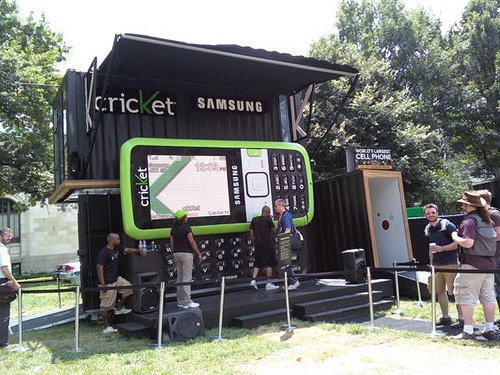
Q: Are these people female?
A: No, they are both male and female.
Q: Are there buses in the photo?
A: No, there are no buses.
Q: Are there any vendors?
A: No, there are no vendors.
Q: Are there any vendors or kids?
A: No, there are no vendors or kids.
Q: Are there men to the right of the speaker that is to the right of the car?
A: Yes, there is a man to the right of the speaker.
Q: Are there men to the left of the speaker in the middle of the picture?
A: No, the man is to the right of the speaker.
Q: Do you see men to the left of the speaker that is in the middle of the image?
A: No, the man is to the right of the speaker.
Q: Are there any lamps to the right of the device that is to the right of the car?
A: No, there is a man to the right of the speaker.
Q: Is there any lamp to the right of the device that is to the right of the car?
A: No, there is a man to the right of the speaker.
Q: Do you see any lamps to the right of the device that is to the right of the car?
A: No, there is a man to the right of the speaker.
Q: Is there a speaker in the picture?
A: Yes, there is a speaker.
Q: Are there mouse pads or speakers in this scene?
A: Yes, there is a speaker.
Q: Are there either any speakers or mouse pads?
A: Yes, there is a speaker.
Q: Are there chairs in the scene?
A: No, there are no chairs.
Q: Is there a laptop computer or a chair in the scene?
A: No, there are no chairs or laptops.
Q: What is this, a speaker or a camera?
A: This is a speaker.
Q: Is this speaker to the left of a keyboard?
A: No, the speaker is to the left of a man.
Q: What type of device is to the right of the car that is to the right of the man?
A: The device is a speaker.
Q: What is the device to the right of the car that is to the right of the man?
A: The device is a speaker.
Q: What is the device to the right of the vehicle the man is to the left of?
A: The device is a speaker.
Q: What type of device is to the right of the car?
A: The device is a speaker.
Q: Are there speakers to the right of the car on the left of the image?
A: Yes, there is a speaker to the right of the car.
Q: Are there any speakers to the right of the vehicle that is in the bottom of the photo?
A: Yes, there is a speaker to the right of the car.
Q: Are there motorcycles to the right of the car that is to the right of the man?
A: No, there is a speaker to the right of the car.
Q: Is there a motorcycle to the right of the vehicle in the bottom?
A: No, there is a speaker to the right of the car.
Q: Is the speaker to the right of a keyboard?
A: No, the speaker is to the right of a car.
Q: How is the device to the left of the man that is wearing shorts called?
A: The device is a speaker.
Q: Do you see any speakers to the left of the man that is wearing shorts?
A: Yes, there is a speaker to the left of the man.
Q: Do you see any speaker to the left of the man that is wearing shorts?
A: Yes, there is a speaker to the left of the man.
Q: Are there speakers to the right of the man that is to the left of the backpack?
A: No, the speaker is to the left of the man.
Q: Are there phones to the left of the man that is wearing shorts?
A: No, there is a speaker to the left of the man.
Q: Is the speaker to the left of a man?
A: Yes, the speaker is to the left of a man.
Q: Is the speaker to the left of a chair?
A: No, the speaker is to the left of a man.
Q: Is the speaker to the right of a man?
A: No, the speaker is to the left of a man.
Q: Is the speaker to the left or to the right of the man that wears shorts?
A: The speaker is to the left of the man.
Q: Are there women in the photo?
A: Yes, there is a woman.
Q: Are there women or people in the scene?
A: Yes, there is a woman.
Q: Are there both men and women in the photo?
A: Yes, there are both a woman and a man.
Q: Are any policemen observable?
A: No, there are no policemen.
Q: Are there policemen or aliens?
A: No, there are no policemen or aliens.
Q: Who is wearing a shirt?
A: The woman is wearing a shirt.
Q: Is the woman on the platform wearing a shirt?
A: Yes, the woman is wearing a shirt.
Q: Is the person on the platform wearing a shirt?
A: Yes, the woman is wearing a shirt.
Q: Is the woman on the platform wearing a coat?
A: No, the woman is wearing a shirt.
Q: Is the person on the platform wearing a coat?
A: No, the woman is wearing a shirt.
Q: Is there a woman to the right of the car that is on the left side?
A: Yes, there is a woman to the right of the car.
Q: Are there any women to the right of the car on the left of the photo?
A: Yes, there is a woman to the right of the car.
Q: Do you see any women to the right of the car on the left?
A: Yes, there is a woman to the right of the car.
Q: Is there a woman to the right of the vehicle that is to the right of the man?
A: Yes, there is a woman to the right of the car.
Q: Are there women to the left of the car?
A: No, the woman is to the right of the car.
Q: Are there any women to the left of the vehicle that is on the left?
A: No, the woman is to the right of the car.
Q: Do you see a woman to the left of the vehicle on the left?
A: No, the woman is to the right of the car.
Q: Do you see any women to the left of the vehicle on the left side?
A: No, the woman is to the right of the car.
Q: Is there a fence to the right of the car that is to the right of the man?
A: No, there is a woman to the right of the car.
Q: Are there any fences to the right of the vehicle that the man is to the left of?
A: No, there is a woman to the right of the car.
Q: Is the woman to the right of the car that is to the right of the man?
A: Yes, the woman is to the right of the car.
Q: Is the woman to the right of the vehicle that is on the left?
A: Yes, the woman is to the right of the car.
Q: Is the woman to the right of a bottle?
A: No, the woman is to the right of the car.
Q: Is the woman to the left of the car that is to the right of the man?
A: No, the woman is to the right of the car.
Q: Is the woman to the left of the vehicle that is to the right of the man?
A: No, the woman is to the right of the car.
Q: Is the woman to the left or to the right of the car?
A: The woman is to the right of the car.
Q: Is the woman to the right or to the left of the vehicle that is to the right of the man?
A: The woman is to the right of the car.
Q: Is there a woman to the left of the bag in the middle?
A: Yes, there is a woman to the left of the bag.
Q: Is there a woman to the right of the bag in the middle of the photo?
A: No, the woman is to the left of the bag.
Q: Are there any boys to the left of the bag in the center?
A: No, there is a woman to the left of the bag.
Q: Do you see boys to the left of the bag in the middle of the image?
A: No, there is a woman to the left of the bag.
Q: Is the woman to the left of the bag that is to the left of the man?
A: Yes, the woman is to the left of the bag.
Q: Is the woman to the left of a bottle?
A: No, the woman is to the left of the bag.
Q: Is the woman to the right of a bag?
A: No, the woman is to the left of a bag.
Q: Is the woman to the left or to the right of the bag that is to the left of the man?
A: The woman is to the left of the bag.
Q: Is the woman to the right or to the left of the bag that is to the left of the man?
A: The woman is to the left of the bag.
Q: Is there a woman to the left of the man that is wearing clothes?
A: Yes, there is a woman to the left of the man.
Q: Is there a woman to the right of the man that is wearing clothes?
A: No, the woman is to the left of the man.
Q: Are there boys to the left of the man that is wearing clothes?
A: No, there is a woman to the left of the man.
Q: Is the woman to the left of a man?
A: Yes, the woman is to the left of a man.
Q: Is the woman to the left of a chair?
A: No, the woman is to the left of a man.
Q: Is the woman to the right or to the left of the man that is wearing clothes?
A: The woman is to the left of the man.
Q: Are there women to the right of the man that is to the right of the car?
A: Yes, there is a woman to the right of the man.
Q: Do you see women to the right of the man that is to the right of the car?
A: Yes, there is a woman to the right of the man.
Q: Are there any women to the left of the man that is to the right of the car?
A: No, the woman is to the right of the man.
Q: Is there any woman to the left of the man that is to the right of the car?
A: No, the woman is to the right of the man.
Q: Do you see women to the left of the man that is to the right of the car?
A: No, the woman is to the right of the man.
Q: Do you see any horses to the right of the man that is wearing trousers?
A: No, there is a woman to the right of the man.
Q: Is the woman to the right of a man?
A: Yes, the woman is to the right of a man.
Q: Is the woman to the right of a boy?
A: No, the woman is to the right of a man.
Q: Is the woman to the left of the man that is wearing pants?
A: No, the woman is to the right of the man.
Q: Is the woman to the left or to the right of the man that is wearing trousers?
A: The woman is to the right of the man.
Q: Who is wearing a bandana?
A: The woman is wearing a bandana.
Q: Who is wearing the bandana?
A: The woman is wearing a bandana.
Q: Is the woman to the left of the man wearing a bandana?
A: Yes, the woman is wearing a bandana.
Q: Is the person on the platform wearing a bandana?
A: Yes, the woman is wearing a bandana.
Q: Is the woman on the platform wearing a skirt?
A: No, the woman is wearing a bandana.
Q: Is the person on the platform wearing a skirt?
A: No, the woman is wearing a bandana.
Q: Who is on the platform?
A: The woman is on the platform.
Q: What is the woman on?
A: The woman is on the platform.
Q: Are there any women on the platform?
A: Yes, there is a woman on the platform.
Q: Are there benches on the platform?
A: No, there is a woman on the platform.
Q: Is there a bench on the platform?
A: No, there is a woman on the platform.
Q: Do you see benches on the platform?
A: No, there is a woman on the platform.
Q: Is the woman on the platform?
A: Yes, the woman is on the platform.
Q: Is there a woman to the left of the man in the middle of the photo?
A: Yes, there is a woman to the left of the man.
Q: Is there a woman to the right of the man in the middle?
A: No, the woman is to the left of the man.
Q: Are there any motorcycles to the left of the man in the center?
A: No, there is a woman to the left of the man.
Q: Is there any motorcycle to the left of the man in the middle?
A: No, there is a woman to the left of the man.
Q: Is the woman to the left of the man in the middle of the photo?
A: Yes, the woman is to the left of the man.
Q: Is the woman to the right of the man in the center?
A: No, the woman is to the left of the man.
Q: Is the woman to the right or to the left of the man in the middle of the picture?
A: The woman is to the left of the man.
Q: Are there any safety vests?
A: No, there are no safety vests.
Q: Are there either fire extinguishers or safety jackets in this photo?
A: No, there are no safety jackets or fire extinguishers.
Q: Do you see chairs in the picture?
A: No, there are no chairs.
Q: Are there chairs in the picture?
A: No, there are no chairs.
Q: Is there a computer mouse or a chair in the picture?
A: No, there are no chairs or computer mice.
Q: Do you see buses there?
A: No, there are no buses.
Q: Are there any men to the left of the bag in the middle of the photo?
A: Yes, there is a man to the left of the bag.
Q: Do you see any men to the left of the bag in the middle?
A: Yes, there is a man to the left of the bag.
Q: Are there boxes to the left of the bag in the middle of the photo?
A: No, there is a man to the left of the bag.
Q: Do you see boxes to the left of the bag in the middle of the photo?
A: No, there is a man to the left of the bag.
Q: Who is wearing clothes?
A: The man is wearing clothes.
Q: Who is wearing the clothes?
A: The man is wearing clothes.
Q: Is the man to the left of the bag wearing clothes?
A: Yes, the man is wearing clothes.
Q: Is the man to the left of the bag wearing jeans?
A: No, the man is wearing clothes.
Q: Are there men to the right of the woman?
A: Yes, there is a man to the right of the woman.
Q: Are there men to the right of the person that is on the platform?
A: Yes, there is a man to the right of the woman.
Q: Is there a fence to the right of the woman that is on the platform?
A: No, there is a man to the right of the woman.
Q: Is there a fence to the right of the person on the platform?
A: No, there is a man to the right of the woman.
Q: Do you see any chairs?
A: No, there are no chairs.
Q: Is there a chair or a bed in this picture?
A: No, there are no chairs or beds.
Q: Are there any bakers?
A: No, there are no bakers.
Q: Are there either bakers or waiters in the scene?
A: No, there are no bakers or waiters.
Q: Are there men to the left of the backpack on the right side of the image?
A: Yes, there is a man to the left of the backpack.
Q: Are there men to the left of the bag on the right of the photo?
A: Yes, there is a man to the left of the backpack.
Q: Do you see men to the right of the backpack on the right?
A: No, the man is to the left of the backpack.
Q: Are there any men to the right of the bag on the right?
A: No, the man is to the left of the backpack.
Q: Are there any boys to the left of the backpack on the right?
A: No, there is a man to the left of the backpack.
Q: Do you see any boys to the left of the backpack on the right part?
A: No, there is a man to the left of the backpack.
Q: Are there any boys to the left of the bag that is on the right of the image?
A: No, there is a man to the left of the backpack.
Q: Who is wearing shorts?
A: The man is wearing shorts.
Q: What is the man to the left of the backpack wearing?
A: The man is wearing shorts.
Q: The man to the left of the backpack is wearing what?
A: The man is wearing shorts.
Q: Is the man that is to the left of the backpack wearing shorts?
A: Yes, the man is wearing shorts.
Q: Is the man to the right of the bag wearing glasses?
A: No, the man is wearing shorts.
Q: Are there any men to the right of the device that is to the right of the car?
A: Yes, there is a man to the right of the speaker.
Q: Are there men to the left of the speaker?
A: No, the man is to the right of the speaker.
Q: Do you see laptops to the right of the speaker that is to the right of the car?
A: No, there is a man to the right of the speaker.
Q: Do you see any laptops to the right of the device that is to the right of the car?
A: No, there is a man to the right of the speaker.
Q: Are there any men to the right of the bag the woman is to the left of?
A: Yes, there is a man to the right of the bag.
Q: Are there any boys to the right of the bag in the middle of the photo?
A: No, there is a man to the right of the bag.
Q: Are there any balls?
A: No, there are no balls.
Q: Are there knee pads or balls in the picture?
A: No, there are no balls or knee pads.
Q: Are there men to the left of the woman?
A: Yes, there is a man to the left of the woman.